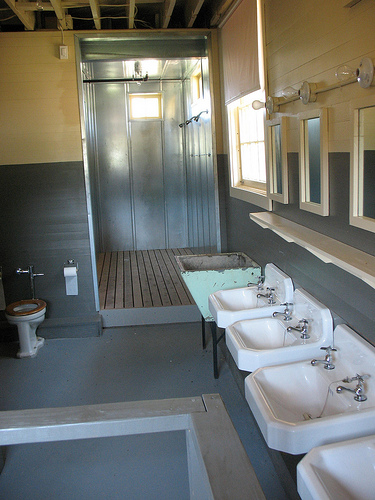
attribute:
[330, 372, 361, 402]
faucet — silver, metal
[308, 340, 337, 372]
faucet — metal, silver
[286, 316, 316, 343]
faucet — silver, metal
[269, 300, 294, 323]
faucet — metal, silver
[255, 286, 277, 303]
faucet — silver, metal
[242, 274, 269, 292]
faucet — metal, silver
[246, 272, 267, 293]
faucet — silver, metal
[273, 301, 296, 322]
faucet — metal, silver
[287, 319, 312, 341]
faucet — metal, silver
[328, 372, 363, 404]
tap — metallic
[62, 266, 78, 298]
tissue — white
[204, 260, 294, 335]
sink — white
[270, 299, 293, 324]
faucet — metal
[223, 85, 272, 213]
window — large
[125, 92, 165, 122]
window — small